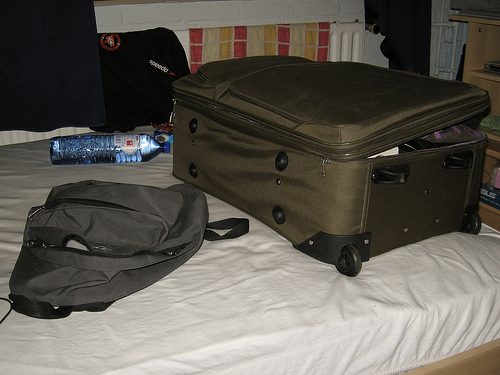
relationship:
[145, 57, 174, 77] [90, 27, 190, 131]
speedo brand on shirt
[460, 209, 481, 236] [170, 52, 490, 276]
wheel on suitcase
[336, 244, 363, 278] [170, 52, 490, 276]
wheel of a suitcase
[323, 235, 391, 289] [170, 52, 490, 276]
wheel of a suitcase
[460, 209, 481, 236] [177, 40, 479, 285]
wheel of a suitcase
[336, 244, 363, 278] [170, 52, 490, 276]
wheel on suitcase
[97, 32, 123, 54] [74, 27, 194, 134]
emblem on shirt